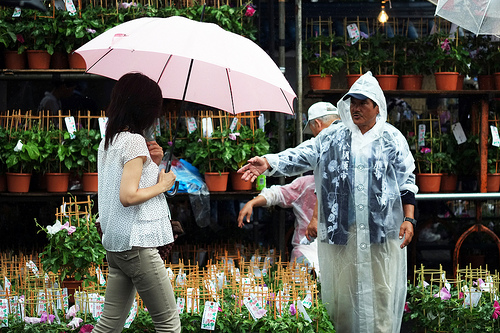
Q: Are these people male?
A: No, they are both male and female.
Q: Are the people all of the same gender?
A: No, they are both male and female.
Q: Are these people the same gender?
A: No, they are both male and female.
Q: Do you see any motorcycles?
A: No, there are no motorcycles.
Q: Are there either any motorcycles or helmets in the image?
A: No, there are no motorcycles or helmets.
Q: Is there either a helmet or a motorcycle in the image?
A: No, there are no motorcycles or helmets.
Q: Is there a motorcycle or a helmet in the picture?
A: No, there are no motorcycles or helmets.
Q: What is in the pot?
A: The plant is in the pot.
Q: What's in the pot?
A: The plant is in the pot.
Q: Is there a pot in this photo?
A: Yes, there is a pot.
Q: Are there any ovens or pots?
A: Yes, there is a pot.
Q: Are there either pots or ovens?
A: Yes, there is a pot.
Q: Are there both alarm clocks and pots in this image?
A: No, there is a pot but no alarm clocks.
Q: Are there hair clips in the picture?
A: No, there are no hair clips.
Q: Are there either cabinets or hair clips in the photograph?
A: No, there are no hair clips or cabinets.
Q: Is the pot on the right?
A: Yes, the pot is on the right of the image.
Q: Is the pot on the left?
A: No, the pot is on the right of the image.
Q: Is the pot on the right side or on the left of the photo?
A: The pot is on the right of the image.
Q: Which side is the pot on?
A: The pot is on the right of the image.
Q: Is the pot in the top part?
A: Yes, the pot is in the top of the image.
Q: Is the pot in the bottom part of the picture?
A: No, the pot is in the top of the image.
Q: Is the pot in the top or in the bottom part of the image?
A: The pot is in the top of the image.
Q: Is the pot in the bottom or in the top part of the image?
A: The pot is in the top of the image.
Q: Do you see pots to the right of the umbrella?
A: Yes, there is a pot to the right of the umbrella.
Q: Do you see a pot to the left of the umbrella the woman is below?
A: No, the pot is to the right of the umbrella.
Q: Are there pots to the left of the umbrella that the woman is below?
A: No, the pot is to the right of the umbrella.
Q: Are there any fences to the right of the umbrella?
A: No, there is a pot to the right of the umbrella.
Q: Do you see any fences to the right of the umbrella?
A: No, there is a pot to the right of the umbrella.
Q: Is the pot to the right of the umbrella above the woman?
A: Yes, the pot is to the right of the umbrella.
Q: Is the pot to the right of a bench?
A: No, the pot is to the right of the umbrella.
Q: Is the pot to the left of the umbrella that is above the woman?
A: No, the pot is to the right of the umbrella.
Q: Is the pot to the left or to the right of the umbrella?
A: The pot is to the right of the umbrella.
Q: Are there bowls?
A: No, there are no bowls.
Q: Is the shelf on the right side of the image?
A: Yes, the shelf is on the right of the image.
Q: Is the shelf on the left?
A: No, the shelf is on the right of the image.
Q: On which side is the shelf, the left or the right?
A: The shelf is on the right of the image.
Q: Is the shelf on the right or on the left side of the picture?
A: The shelf is on the right of the image.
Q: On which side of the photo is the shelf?
A: The shelf is on the right of the image.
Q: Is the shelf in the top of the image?
A: Yes, the shelf is in the top of the image.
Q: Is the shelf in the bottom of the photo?
A: No, the shelf is in the top of the image.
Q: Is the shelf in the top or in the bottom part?
A: The shelf is in the top of the image.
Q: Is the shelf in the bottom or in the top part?
A: The shelf is in the top of the image.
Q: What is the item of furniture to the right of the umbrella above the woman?
A: The piece of furniture is a shelf.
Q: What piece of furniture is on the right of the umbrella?
A: The piece of furniture is a shelf.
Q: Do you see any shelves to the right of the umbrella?
A: Yes, there is a shelf to the right of the umbrella.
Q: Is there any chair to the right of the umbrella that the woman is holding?
A: No, there is a shelf to the right of the umbrella.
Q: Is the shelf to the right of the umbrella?
A: Yes, the shelf is to the right of the umbrella.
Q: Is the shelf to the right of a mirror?
A: No, the shelf is to the right of the umbrella.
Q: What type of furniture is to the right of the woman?
A: The piece of furniture is a shelf.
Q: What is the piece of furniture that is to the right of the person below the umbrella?
A: The piece of furniture is a shelf.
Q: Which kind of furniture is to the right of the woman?
A: The piece of furniture is a shelf.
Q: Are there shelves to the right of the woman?
A: Yes, there is a shelf to the right of the woman.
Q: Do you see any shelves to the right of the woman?
A: Yes, there is a shelf to the right of the woman.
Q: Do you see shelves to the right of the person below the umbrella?
A: Yes, there is a shelf to the right of the woman.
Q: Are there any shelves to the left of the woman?
A: No, the shelf is to the right of the woman.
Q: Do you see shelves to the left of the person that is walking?
A: No, the shelf is to the right of the woman.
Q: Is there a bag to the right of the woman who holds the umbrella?
A: No, there is a shelf to the right of the woman.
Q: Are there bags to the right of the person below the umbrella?
A: No, there is a shelf to the right of the woman.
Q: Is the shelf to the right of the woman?
A: Yes, the shelf is to the right of the woman.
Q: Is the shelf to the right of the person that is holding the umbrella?
A: Yes, the shelf is to the right of the woman.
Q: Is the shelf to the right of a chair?
A: No, the shelf is to the right of the woman.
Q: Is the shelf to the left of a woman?
A: No, the shelf is to the right of a woman.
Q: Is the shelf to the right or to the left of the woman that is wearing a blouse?
A: The shelf is to the right of the woman.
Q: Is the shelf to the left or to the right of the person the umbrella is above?
A: The shelf is to the right of the woman.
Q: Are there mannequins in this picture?
A: No, there are no mannequins.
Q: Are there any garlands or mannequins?
A: No, there are no mannequins or garlands.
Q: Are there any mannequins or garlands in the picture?
A: No, there are no mannequins or garlands.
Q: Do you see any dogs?
A: No, there are no dogs.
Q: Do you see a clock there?
A: No, there are no clocks.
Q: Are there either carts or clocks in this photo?
A: No, there are no clocks or carts.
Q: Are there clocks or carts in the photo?
A: No, there are no clocks or carts.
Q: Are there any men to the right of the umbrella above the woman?
A: Yes, there is a man to the right of the umbrella.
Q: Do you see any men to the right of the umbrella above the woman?
A: Yes, there is a man to the right of the umbrella.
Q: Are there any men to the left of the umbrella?
A: No, the man is to the right of the umbrella.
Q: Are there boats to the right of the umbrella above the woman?
A: No, there is a man to the right of the umbrella.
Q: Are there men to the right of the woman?
A: Yes, there is a man to the right of the woman.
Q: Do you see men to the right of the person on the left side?
A: Yes, there is a man to the right of the woman.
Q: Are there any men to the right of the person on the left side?
A: Yes, there is a man to the right of the woman.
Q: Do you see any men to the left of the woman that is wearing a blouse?
A: No, the man is to the right of the woman.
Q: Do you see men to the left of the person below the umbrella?
A: No, the man is to the right of the woman.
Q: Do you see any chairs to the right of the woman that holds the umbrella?
A: No, there is a man to the right of the woman.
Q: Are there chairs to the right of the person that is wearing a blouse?
A: No, there is a man to the right of the woman.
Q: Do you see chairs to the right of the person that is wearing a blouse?
A: No, there is a man to the right of the woman.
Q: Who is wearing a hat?
A: The man is wearing a hat.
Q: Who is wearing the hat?
A: The man is wearing a hat.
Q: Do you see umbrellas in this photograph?
A: Yes, there is an umbrella.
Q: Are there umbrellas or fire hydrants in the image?
A: Yes, there is an umbrella.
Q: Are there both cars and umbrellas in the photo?
A: No, there is an umbrella but no cars.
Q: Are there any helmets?
A: No, there are no helmets.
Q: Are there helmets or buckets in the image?
A: No, there are no helmets or buckets.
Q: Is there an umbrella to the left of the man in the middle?
A: Yes, there is an umbrella to the left of the man.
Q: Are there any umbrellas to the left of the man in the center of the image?
A: Yes, there is an umbrella to the left of the man.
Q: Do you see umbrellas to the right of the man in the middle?
A: No, the umbrella is to the left of the man.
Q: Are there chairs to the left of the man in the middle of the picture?
A: No, there is an umbrella to the left of the man.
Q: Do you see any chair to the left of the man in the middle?
A: No, there is an umbrella to the left of the man.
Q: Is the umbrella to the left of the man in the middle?
A: Yes, the umbrella is to the left of the man.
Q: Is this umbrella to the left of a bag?
A: No, the umbrella is to the left of the man.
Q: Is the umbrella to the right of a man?
A: No, the umbrella is to the left of a man.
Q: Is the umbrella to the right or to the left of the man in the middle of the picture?
A: The umbrella is to the left of the man.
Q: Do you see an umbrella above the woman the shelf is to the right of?
A: Yes, there is an umbrella above the woman.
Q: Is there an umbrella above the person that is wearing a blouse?
A: Yes, there is an umbrella above the woman.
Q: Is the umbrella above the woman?
A: Yes, the umbrella is above the woman.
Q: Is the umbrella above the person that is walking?
A: Yes, the umbrella is above the woman.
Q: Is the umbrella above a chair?
A: No, the umbrella is above the woman.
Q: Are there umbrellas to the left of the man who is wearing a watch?
A: Yes, there is an umbrella to the left of the man.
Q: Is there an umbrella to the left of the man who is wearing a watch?
A: Yes, there is an umbrella to the left of the man.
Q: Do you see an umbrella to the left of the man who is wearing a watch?
A: Yes, there is an umbrella to the left of the man.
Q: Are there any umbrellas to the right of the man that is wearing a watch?
A: No, the umbrella is to the left of the man.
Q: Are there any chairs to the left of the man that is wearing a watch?
A: No, there is an umbrella to the left of the man.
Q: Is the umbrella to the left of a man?
A: Yes, the umbrella is to the left of a man.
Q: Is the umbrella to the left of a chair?
A: No, the umbrella is to the left of a man.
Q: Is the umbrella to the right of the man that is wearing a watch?
A: No, the umbrella is to the left of the man.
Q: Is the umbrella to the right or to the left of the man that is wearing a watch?
A: The umbrella is to the left of the man.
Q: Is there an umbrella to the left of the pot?
A: Yes, there is an umbrella to the left of the pot.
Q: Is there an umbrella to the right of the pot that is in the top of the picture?
A: No, the umbrella is to the left of the pot.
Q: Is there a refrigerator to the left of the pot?
A: No, there is an umbrella to the left of the pot.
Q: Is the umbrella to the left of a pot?
A: Yes, the umbrella is to the left of a pot.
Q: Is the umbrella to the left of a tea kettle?
A: No, the umbrella is to the left of a pot.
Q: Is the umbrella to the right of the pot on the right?
A: No, the umbrella is to the left of the pot.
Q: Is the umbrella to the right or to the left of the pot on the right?
A: The umbrella is to the left of the pot.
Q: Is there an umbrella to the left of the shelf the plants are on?
A: Yes, there is an umbrella to the left of the shelf.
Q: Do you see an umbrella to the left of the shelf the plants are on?
A: Yes, there is an umbrella to the left of the shelf.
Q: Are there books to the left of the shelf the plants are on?
A: No, there is an umbrella to the left of the shelf.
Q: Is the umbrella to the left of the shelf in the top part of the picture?
A: Yes, the umbrella is to the left of the shelf.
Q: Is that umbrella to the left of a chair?
A: No, the umbrella is to the left of the shelf.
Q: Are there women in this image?
A: Yes, there is a woman.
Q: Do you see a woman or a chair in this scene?
A: Yes, there is a woman.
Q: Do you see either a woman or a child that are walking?
A: Yes, the woman is walking.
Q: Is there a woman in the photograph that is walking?
A: Yes, there is a woman that is walking.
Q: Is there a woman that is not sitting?
A: Yes, there is a woman that is walking.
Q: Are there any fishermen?
A: No, there are no fishermen.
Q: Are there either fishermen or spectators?
A: No, there are no fishermen or spectators.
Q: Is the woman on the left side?
A: Yes, the woman is on the left of the image.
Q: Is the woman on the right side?
A: No, the woman is on the left of the image.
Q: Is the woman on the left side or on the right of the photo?
A: The woman is on the left of the image.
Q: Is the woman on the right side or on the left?
A: The woman is on the left of the image.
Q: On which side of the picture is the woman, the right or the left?
A: The woman is on the left of the image.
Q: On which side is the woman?
A: The woman is on the left of the image.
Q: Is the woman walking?
A: Yes, the woman is walking.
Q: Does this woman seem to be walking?
A: Yes, the woman is walking.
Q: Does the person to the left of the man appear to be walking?
A: Yes, the woman is walking.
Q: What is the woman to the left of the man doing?
A: The woman is walking.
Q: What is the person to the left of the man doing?
A: The woman is walking.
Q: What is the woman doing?
A: The woman is walking.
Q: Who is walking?
A: The woman is walking.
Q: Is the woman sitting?
A: No, the woman is walking.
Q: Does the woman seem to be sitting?
A: No, the woman is walking.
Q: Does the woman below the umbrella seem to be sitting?
A: No, the woman is walking.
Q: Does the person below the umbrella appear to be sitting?
A: No, the woman is walking.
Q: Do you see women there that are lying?
A: No, there is a woman but she is walking.